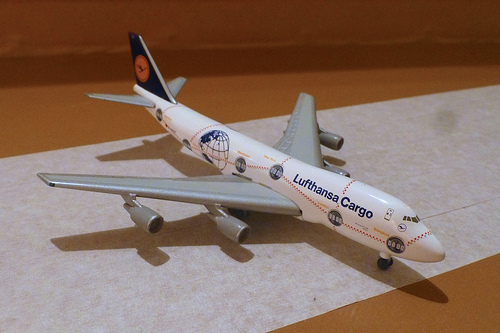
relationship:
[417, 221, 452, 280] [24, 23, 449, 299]
nose of plane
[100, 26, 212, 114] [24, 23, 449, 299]
tail of plane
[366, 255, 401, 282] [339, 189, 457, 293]
gear in front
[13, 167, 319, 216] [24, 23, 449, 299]
wing of plane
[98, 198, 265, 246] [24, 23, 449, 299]
engine of plane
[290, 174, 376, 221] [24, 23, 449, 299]
lufthansa cargo on airplane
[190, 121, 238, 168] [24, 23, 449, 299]
globe on model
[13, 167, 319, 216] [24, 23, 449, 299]
wing on model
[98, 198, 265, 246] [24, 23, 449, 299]
engines on model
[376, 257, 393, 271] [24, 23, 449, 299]
gear on model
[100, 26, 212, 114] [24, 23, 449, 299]
tail of model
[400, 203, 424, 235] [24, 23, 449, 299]
windows on model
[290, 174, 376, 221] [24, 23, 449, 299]
name on model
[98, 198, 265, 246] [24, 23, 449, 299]
engine on model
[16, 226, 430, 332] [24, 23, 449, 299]
shadow of model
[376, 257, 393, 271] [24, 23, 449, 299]
gear of model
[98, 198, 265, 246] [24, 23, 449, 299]
engine on jet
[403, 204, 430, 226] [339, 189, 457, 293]
windshield in front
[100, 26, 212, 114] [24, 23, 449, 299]
tail of jet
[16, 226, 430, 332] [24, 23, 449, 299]
shadow of jet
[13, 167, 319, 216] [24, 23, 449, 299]
wing of jet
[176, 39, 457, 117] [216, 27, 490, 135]
reflection of light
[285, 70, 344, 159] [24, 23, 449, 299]
booster on jet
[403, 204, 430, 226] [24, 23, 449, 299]
windshield on plane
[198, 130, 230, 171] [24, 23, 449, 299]
globe on plane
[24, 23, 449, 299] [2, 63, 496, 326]
model on shelf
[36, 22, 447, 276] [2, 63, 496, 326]
airplane on shelf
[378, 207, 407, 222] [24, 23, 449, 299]
decal on airplane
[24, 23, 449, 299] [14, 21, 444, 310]
model displayed on table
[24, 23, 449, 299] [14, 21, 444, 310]
model on table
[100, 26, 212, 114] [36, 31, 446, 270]
tail on rear of airplane